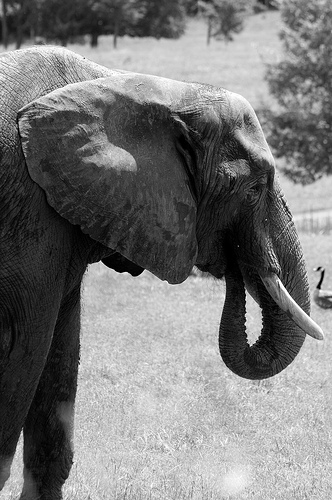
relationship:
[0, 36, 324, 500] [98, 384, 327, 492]
elephant walking on grass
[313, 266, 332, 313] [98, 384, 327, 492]
bird walking on grass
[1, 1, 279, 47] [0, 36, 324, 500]
trees behind elephant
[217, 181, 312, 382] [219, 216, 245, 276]
trunk going into elephant's mouth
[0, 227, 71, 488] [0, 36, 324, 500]
front leg of elephant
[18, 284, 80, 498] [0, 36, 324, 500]
front leg of elephant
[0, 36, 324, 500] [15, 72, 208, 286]
elephant has ear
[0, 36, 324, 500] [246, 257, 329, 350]
elephant has tusks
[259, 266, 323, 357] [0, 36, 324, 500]
tusk of elephant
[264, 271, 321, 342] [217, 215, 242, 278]
trunk in elephant's mouth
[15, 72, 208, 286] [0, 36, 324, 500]
ear of elephant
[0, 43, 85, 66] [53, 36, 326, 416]
hump on elephant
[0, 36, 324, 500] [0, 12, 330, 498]
elephant in field of grass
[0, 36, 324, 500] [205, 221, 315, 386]
elephant has trunk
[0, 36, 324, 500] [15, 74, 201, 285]
elephant has ears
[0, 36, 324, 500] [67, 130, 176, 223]
elephant has skin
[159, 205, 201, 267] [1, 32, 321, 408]
mud on elephant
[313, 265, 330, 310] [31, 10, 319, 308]
bird in background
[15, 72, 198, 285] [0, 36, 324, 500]
ear of elephant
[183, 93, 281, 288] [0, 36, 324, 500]
head of elephant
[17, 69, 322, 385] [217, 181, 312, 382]
elephant has trunk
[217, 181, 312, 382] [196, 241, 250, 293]
trunk in mouth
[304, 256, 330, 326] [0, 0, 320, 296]
goose in background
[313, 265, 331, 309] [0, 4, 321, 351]
fowl in background